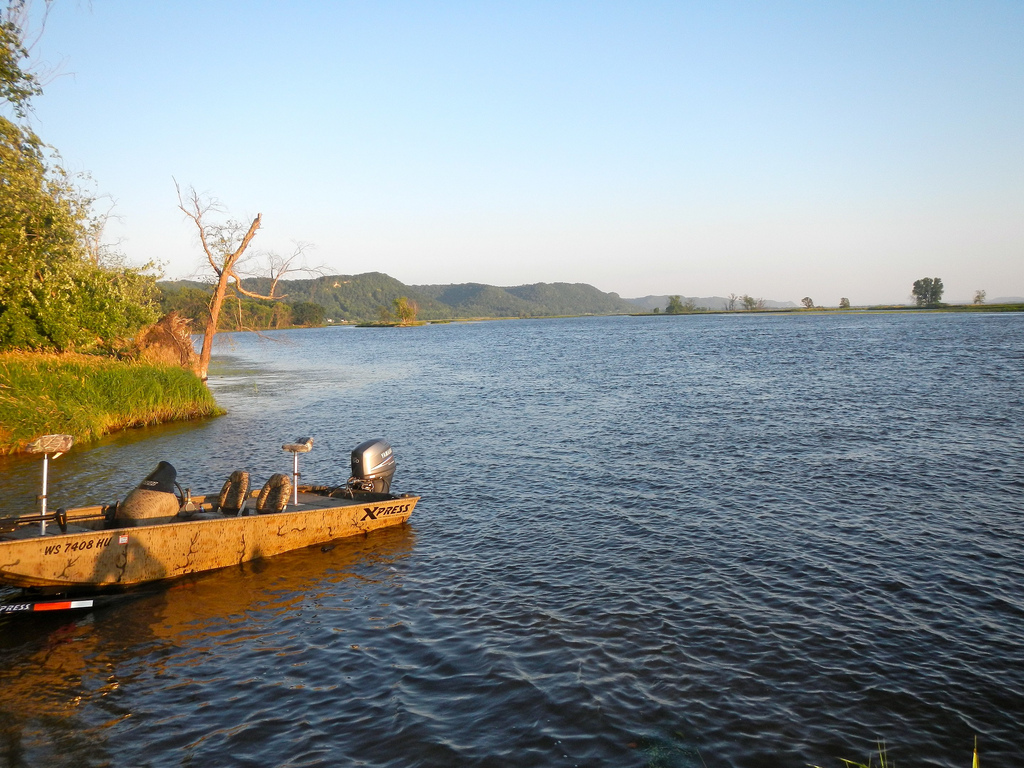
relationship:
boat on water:
[6, 409, 430, 593] [525, 433, 865, 729]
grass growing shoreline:
[23, 363, 184, 431] [60, 389, 208, 459]